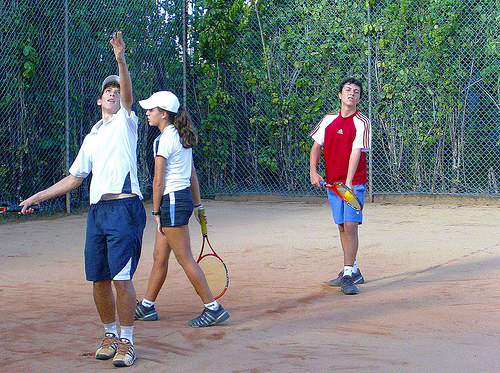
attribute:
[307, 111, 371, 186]
shirt — red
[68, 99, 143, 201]
shirt — white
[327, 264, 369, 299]
shoes — blue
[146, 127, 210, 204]
shirt — white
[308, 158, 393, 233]
shorts — blue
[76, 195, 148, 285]
shorts — navy, white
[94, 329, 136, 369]
shoes — tan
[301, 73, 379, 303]
boy — white